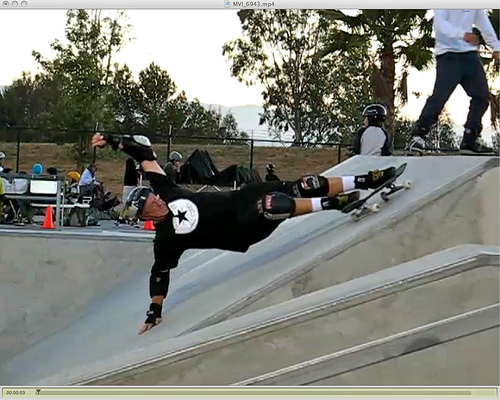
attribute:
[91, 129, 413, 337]
skater — tricking, older, skating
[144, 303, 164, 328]
wristguard — black, down, protective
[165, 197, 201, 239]
logo — white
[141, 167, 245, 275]
shirt — black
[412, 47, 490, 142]
pants — grey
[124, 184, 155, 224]
helmet — black, protective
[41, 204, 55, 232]
cone — orange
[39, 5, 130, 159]
tree — green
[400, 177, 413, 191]
wheel — white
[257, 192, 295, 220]
kneepad — black, protective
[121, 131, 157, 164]
elbowpad — protective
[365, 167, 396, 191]
shoe — black